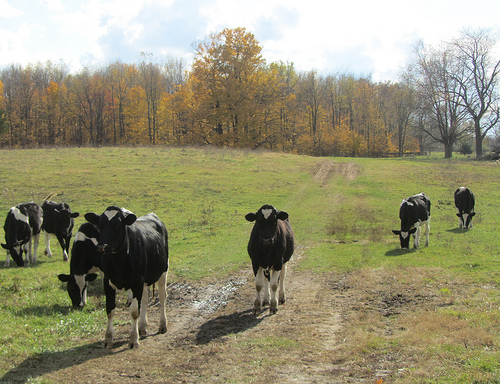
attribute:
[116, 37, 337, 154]
trees — yellow, brown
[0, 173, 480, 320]
cows — black and white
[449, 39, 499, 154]
tree — bare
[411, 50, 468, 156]
tree — bare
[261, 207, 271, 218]
spot — white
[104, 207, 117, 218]
spot — white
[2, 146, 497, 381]
grass — green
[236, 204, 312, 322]
cow — straight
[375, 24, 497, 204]
trees — bare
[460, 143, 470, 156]
green tree — small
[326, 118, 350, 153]
tree — yellow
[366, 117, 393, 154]
tree — yellow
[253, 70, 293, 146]
tree — yellow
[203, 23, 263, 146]
tree — yellow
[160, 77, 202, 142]
tree — yellow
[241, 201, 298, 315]
cow — black and white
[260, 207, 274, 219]
triangle — white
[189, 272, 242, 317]
puddle — muddy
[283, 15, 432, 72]
sky — clear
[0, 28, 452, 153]
leaves — yellowing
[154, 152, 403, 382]
tracks — dirt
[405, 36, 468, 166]
tree — bare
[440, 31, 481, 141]
tree — bare